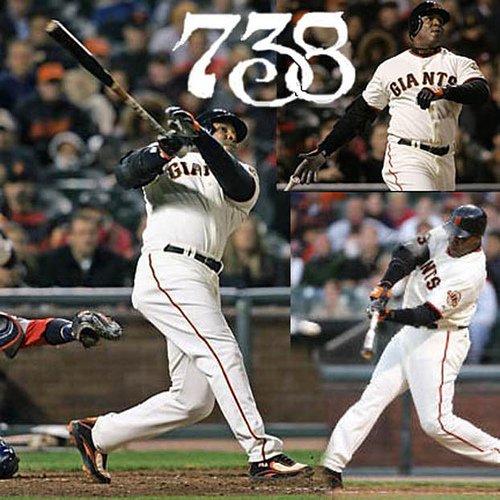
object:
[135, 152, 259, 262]
shirt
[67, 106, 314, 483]
man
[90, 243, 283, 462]
long pants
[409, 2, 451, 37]
helmet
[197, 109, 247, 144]
helmet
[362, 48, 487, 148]
shirt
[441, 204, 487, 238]
helmet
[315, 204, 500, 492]
person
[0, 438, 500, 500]
ground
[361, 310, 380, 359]
bat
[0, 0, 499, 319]
crowd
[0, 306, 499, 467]
stands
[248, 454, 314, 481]
shoe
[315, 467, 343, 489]
shoe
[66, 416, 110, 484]
shoe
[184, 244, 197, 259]
loop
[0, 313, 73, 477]
person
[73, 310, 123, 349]
baseball glove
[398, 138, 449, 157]
belt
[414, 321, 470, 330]
belt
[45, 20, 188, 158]
bat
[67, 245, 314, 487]
pant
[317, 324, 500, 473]
pant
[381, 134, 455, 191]
pant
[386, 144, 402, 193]
stripe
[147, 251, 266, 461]
stripe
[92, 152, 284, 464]
uniform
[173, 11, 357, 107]
number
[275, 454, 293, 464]
lace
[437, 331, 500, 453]
stripe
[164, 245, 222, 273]
belt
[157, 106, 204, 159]
gloves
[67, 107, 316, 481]
batter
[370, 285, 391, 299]
panel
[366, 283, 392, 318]
gloves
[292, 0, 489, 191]
man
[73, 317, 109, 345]
hand